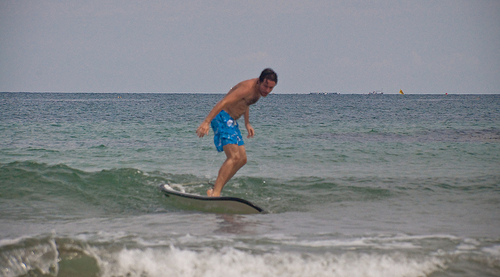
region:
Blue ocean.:
[1, 91, 499, 276]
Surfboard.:
[157, 181, 264, 213]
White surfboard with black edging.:
[160, 181, 266, 212]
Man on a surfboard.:
[158, 67, 278, 212]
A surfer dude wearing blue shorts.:
[160, 66, 276, 214]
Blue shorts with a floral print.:
[210, 108, 242, 149]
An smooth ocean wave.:
[0, 161, 496, 214]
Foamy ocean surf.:
[0, 231, 497, 273]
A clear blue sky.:
[0, 0, 497, 91]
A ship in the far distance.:
[308, 90, 341, 96]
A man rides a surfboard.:
[152, 63, 310, 216]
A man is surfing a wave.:
[138, 56, 306, 226]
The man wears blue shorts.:
[208, 107, 254, 157]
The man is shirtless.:
[198, 74, 258, 144]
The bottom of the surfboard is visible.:
[156, 180, 279, 224]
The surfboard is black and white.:
[155, 177, 278, 220]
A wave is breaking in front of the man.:
[0, 225, 498, 274]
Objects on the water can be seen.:
[295, 80, 455, 100]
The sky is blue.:
[1, 0, 498, 72]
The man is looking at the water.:
[158, 47, 297, 221]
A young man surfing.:
[156, 65, 325, 240]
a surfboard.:
[130, 186, 307, 231]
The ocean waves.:
[322, 101, 472, 197]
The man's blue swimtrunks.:
[191, 101, 262, 165]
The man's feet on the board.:
[161, 174, 294, 220]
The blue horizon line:
[301, 52, 458, 137]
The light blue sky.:
[115, 25, 272, 82]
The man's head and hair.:
[253, 55, 297, 115]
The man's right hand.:
[183, 105, 213, 140]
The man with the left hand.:
[240, 115, 264, 142]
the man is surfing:
[157, 66, 278, 212]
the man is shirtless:
[203, 68, 268, 132]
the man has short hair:
[258, 67, 276, 97]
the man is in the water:
[1, 89, 497, 275]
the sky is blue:
[0, 0, 499, 93]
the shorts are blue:
[208, 105, 243, 151]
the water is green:
[0, 93, 497, 272]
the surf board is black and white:
[161, 184, 263, 215]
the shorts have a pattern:
[208, 112, 248, 152]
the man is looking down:
[166, 68, 275, 213]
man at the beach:
[189, 57, 283, 205]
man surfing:
[167, 69, 301, 216]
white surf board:
[157, 180, 288, 222]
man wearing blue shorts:
[196, 72, 284, 198]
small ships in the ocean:
[307, 84, 434, 119]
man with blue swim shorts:
[153, 66, 309, 217]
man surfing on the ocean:
[142, 61, 322, 228]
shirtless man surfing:
[161, 52, 280, 217]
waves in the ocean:
[5, 59, 160, 266]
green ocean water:
[0, 25, 163, 260]